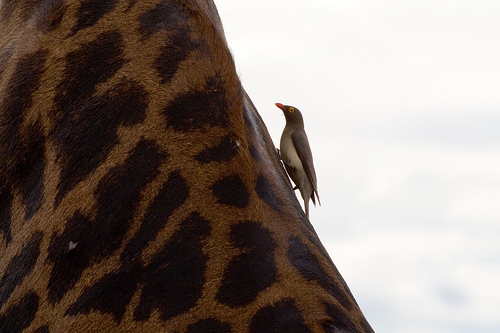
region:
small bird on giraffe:
[258, 86, 328, 228]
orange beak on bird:
[271, 98, 284, 114]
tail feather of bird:
[296, 196, 320, 222]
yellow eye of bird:
[284, 102, 298, 119]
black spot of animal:
[208, 175, 255, 212]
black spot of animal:
[206, 136, 241, 164]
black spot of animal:
[169, 87, 231, 140]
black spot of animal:
[281, 251, 340, 304]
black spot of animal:
[3, 238, 51, 286]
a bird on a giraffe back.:
[263, 86, 333, 226]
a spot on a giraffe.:
[210, 210, 286, 317]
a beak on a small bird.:
[275, 97, 288, 119]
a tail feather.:
[297, 184, 320, 219]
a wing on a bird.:
[291, 128, 328, 204]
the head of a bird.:
[278, 108, 306, 138]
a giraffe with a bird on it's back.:
[0, 1, 377, 331]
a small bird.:
[272, 84, 333, 227]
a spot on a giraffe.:
[275, 227, 365, 289]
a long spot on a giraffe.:
[39, 136, 173, 303]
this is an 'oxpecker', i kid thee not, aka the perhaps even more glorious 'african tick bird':
[265, 93, 328, 229]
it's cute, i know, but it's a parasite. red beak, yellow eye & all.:
[266, 97, 321, 226]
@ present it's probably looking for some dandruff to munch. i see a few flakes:
[63, 83, 256, 258]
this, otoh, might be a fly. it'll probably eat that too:
[63, 233, 83, 260]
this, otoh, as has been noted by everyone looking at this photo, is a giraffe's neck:
[0, 0, 387, 332]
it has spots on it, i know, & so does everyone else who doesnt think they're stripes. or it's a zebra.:
[12, 0, 238, 105]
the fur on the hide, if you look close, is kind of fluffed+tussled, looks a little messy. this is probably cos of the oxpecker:
[3, 3, 238, 83]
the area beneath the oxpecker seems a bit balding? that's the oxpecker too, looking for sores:
[235, 88, 318, 243]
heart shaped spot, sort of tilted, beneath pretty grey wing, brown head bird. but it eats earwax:
[205, 96, 327, 318]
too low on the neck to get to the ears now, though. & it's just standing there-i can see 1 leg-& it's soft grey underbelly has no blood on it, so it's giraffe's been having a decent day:
[262, 123, 308, 213]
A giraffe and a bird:
[3, 3, 379, 331]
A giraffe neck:
[3, 1, 368, 331]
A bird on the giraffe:
[269, 88, 347, 208]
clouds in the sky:
[236, 7, 496, 322]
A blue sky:
[373, 287, 480, 332]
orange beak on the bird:
[272, 98, 284, 114]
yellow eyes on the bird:
[288, 104, 297, 115]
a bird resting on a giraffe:
[250, 87, 333, 224]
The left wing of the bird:
[292, 127, 321, 187]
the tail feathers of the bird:
[303, 190, 320, 226]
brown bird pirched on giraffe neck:
[269, 97, 320, 214]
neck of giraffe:
[1, 0, 381, 332]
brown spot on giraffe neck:
[212, 220, 281, 309]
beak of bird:
[272, 98, 287, 113]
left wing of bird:
[290, 127, 317, 202]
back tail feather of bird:
[301, 188, 316, 218]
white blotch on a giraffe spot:
[64, 236, 79, 251]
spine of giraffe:
[183, 2, 368, 332]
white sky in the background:
[189, 1, 497, 328]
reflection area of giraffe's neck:
[241, 92, 298, 219]